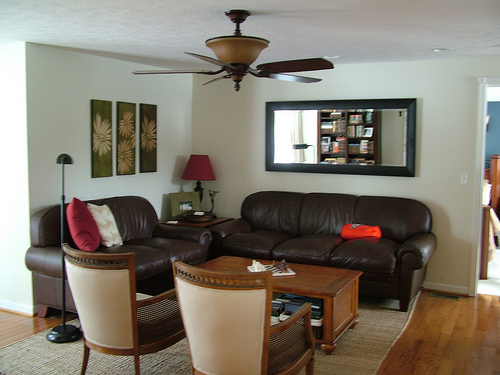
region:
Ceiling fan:
[131, 23, 335, 93]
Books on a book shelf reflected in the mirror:
[314, 107, 381, 167]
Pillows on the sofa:
[66, 195, 124, 252]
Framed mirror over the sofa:
[263, 97, 418, 175]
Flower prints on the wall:
[89, 97, 160, 181]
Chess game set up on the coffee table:
[242, 257, 294, 278]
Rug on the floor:
[2, 280, 423, 373]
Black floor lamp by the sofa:
[45, 152, 84, 347]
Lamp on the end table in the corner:
[178, 150, 215, 210]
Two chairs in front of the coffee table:
[59, 242, 315, 371]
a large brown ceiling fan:
[147, 6, 334, 100]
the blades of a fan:
[262, 55, 347, 109]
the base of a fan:
[217, 9, 259, 21]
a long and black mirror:
[237, 86, 429, 187]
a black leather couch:
[228, 189, 439, 291]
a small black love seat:
[40, 199, 182, 273]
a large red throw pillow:
[65, 209, 100, 246]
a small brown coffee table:
[195, 248, 367, 336]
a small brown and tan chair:
[28, 255, 173, 362]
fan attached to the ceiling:
[128, 10, 340, 106]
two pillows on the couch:
[61, 197, 136, 251]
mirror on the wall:
[244, 98, 432, 182]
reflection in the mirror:
[256, 93, 431, 183]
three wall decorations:
[78, 93, 162, 182]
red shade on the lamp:
[179, 144, 219, 206]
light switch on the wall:
[454, 168, 470, 185]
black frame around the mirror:
[255, 97, 425, 177]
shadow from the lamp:
[168, 153, 193, 193]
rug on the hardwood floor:
[0, 286, 478, 373]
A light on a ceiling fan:
[197, 27, 272, 103]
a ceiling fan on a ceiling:
[112, 8, 355, 101]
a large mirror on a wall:
[252, 92, 441, 187]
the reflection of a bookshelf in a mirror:
[302, 112, 380, 155]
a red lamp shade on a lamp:
[178, 144, 220, 191]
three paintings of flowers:
[80, 92, 168, 182]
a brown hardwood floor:
[440, 315, 482, 362]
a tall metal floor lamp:
[40, 140, 85, 352]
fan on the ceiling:
[115, 33, 332, 121]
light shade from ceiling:
[201, 22, 275, 63]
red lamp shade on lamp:
[174, 146, 219, 184]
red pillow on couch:
[55, 198, 109, 248]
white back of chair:
[160, 281, 275, 372]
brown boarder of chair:
[185, 272, 259, 297]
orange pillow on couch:
[321, 218, 385, 252]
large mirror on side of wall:
[248, 93, 429, 178]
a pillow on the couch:
[338, 214, 379, 259]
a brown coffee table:
[185, 238, 386, 350]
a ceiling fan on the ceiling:
[166, 24, 315, 89]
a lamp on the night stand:
[183, 139, 235, 233]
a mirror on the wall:
[236, 73, 481, 200]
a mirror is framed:
[228, 96, 420, 175]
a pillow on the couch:
[82, 197, 142, 261]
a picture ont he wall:
[80, 106, 107, 168]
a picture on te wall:
[114, 90, 136, 169]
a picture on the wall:
[133, 103, 159, 164]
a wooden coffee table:
[211, 234, 420, 372]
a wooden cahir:
[182, 242, 310, 373]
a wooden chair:
[48, 251, 195, 373]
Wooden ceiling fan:
[132, 10, 335, 96]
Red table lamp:
[182, 153, 217, 219]